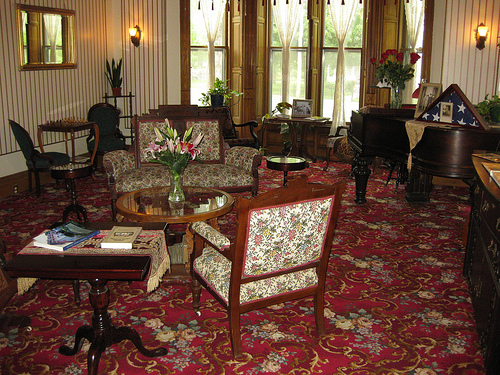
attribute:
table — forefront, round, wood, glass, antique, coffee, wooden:
[133, 186, 229, 221]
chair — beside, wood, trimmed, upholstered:
[206, 199, 329, 322]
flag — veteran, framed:
[429, 88, 492, 128]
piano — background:
[357, 115, 475, 194]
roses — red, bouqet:
[371, 51, 434, 79]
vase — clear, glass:
[378, 80, 424, 113]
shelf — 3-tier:
[107, 91, 153, 140]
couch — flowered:
[124, 142, 184, 184]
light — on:
[97, 16, 184, 75]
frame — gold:
[8, 29, 40, 68]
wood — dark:
[26, 222, 112, 297]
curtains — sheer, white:
[191, 7, 255, 87]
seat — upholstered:
[107, 132, 262, 221]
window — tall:
[181, 2, 333, 140]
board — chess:
[141, 193, 188, 217]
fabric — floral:
[190, 120, 251, 182]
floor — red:
[368, 240, 450, 337]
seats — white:
[212, 216, 322, 282]